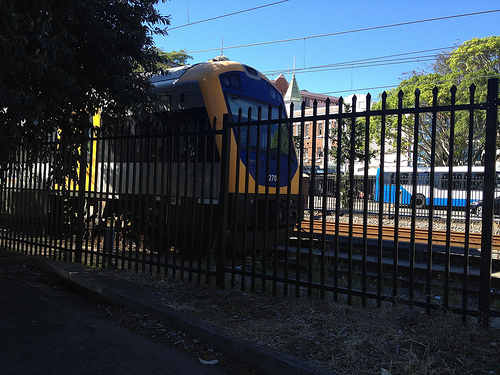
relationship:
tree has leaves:
[48, 24, 141, 160] [3, 44, 98, 155]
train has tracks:
[1, 47, 302, 274] [320, 241, 484, 315]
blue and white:
[241, 82, 287, 143] [145, 149, 214, 184]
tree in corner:
[48, 24, 141, 160] [3, 44, 98, 155]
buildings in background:
[269, 93, 387, 179] [262, 58, 484, 219]